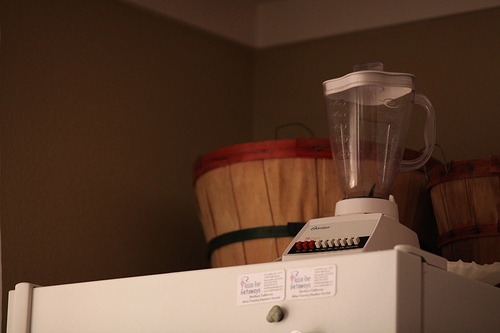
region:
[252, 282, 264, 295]
warning notes are written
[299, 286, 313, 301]
the notes are written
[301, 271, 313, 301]
the notes are written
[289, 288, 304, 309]
the notes are written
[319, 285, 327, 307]
the notes are written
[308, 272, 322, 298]
the notes are written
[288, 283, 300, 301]
the notes are written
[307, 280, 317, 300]
the notes are written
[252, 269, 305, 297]
the notes are written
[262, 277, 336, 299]
the notes are written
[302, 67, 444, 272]
The blender is white.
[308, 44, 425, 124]
The lid is white.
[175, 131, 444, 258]
The basket is tan.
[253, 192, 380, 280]
The buttons are white and red.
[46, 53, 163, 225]
The wall is tan.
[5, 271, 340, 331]
The refrigerator is white.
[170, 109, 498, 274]
Two baskets are on the refrigerator.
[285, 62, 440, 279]
The blender is on the refrigerator.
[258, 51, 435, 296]
The blender is empty.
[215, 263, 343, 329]
Two magnets are on the refrigerator.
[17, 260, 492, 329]
top of a refrigerator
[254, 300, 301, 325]
a magnet on a refrigerator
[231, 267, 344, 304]
two business card on a refrigerator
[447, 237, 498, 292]
white coffee filters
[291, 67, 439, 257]
a white blender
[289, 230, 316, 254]
three red buttons on a blender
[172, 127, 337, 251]
a basket with a red edge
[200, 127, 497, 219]
two baskets on a fridge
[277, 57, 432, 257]
a blender on a fridge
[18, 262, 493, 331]
top of a white fridge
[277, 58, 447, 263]
a white plastic blender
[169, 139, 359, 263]
a fragile fruit basket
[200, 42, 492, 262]
two baskets and a blender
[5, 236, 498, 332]
a tall white refrigerator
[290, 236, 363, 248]
red and white blender buttons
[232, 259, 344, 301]
two cards on a fridge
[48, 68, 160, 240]
a dark green texture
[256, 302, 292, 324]
a fridge magnet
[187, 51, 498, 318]
baskets and a blender on a fridge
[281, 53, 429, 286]
white blender on top of fridge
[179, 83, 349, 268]
barrel basket with red top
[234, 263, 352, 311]
two white business cards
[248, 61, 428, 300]
blender with red and white buttons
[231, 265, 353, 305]
two magnets on a fridge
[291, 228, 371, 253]
buttons of a blender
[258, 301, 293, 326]
rock-shaped magnet